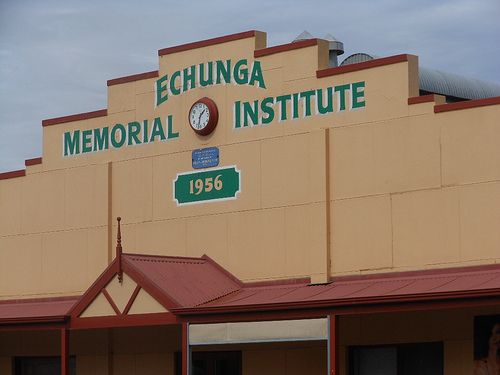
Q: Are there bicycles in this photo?
A: No, there are no bicycles.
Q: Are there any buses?
A: No, there are no buses.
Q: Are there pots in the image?
A: No, there are no pots.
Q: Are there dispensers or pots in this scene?
A: No, there are no pots or dispensers.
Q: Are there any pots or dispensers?
A: No, there are no pots or dispensers.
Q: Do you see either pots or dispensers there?
A: No, there are no pots or dispensers.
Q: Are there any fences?
A: No, there are no fences.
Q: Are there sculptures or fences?
A: No, there are no fences or sculptures.